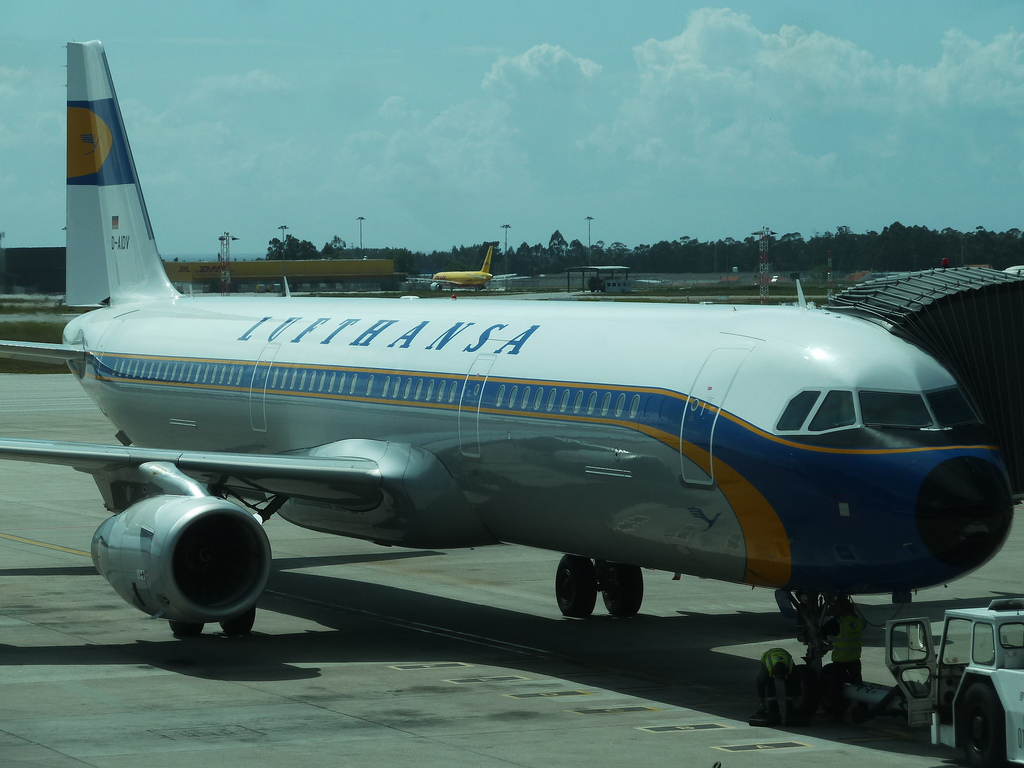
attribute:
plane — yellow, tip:
[15, 32, 994, 717]